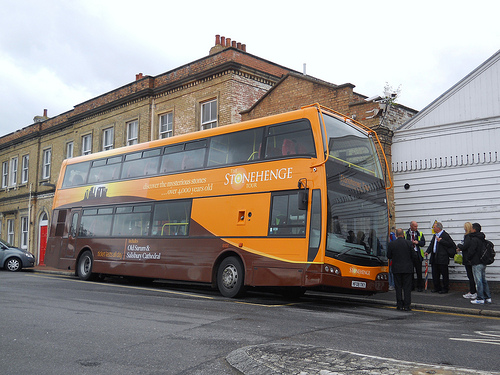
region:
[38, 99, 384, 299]
bus with upper and lower levels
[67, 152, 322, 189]
upper level of bus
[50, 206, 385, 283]
lower level of bus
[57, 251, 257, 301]
wheels on the bus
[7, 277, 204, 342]
road vehicles travel on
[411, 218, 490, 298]
people on the sidewalk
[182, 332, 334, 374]
island of concrete in street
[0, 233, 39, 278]
vehicle on the street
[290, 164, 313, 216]
mirror on the bus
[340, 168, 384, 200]
bus route and information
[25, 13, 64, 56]
this is the sky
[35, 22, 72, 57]
the sky is blue in color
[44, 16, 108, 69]
the sky has clouds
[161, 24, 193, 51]
the clouds are white in color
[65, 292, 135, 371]
this is the road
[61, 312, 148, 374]
the road is grey in color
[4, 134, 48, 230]
this is a building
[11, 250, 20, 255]
the car is grey in color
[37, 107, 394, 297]
this is a bus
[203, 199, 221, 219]
the bus is orange in color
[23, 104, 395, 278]
tall yellow and marron double decker bus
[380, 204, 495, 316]
people standing on sidewalk outside of bus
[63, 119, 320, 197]
top level passenger windows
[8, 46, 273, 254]
large brick building with white windows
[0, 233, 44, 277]
silver car parked on street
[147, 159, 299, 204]
white lettering on bus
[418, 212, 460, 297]
man holding an umbrella by his side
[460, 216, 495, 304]
man wearing blue jeans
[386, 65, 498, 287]
large white building behind people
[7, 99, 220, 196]
long row of white windows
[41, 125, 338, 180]
top part of the bus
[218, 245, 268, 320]
front tire of bus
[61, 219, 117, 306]
back tire of the bus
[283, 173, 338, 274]
a door of the bus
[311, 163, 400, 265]
front glass of bus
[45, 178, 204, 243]
side window of the bus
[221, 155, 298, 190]
name on the bus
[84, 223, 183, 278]
name of the bus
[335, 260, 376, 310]
number plate of bus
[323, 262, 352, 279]
light of the bus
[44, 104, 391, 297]
A yellow and brown bus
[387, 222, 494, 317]
People standing near a bus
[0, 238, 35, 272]
Front end of a silver car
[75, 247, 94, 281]
Rear wheel on a bus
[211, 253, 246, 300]
The front wheel of a bus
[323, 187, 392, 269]
Front windshield of a bus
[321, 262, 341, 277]
Three lights on the front of a bus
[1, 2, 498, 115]
A bright, cloudy sky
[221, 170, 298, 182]
White letters on a bus's side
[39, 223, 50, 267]
Red door of a building